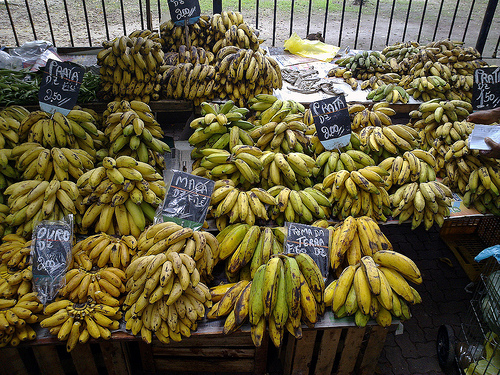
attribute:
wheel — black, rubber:
[441, 316, 461, 370]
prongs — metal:
[457, 258, 498, 372]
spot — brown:
[155, 258, 176, 285]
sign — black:
[309, 94, 350, 152]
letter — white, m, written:
[306, 100, 322, 120]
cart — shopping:
[431, 237, 499, 375]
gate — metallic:
[1, 0, 499, 71]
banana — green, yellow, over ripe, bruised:
[227, 154, 261, 185]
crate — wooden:
[279, 282, 386, 375]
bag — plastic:
[9, 46, 45, 65]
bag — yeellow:
[284, 26, 339, 66]